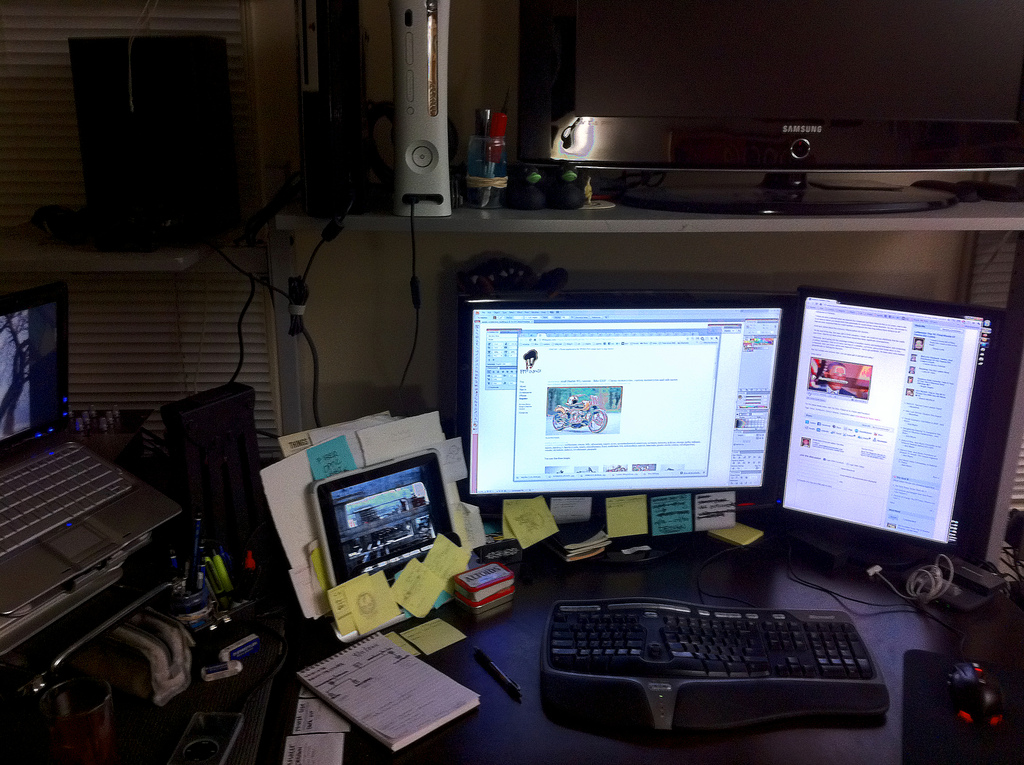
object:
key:
[699, 617, 715, 629]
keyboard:
[544, 603, 875, 683]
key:
[613, 612, 645, 639]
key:
[737, 636, 750, 645]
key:
[767, 641, 797, 666]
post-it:
[328, 570, 402, 636]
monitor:
[306, 445, 471, 642]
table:
[206, 532, 957, 765]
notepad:
[291, 633, 480, 753]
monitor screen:
[469, 300, 801, 497]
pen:
[465, 641, 526, 699]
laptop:
[0, 294, 184, 613]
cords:
[173, 214, 362, 391]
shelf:
[0, 164, 358, 262]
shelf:
[356, 0, 517, 215]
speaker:
[392, 0, 457, 215]